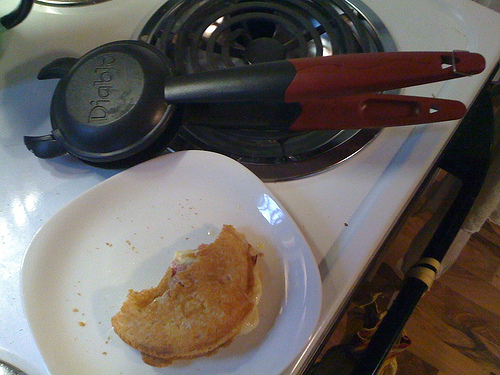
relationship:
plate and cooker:
[21, 148, 326, 373] [23, 0, 485, 183]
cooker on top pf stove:
[23, 0, 485, 183] [3, 0, 498, 373]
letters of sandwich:
[81, 46, 128, 128] [91, 222, 275, 373]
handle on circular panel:
[174, 46, 486, 132] [23, 39, 167, 168]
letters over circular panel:
[81, 46, 128, 128] [20, 36, 160, 168]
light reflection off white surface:
[1, 171, 41, 282] [0, 4, 498, 352]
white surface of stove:
[0, 4, 498, 352] [3, 0, 498, 373]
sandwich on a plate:
[109, 220, 264, 370] [21, 148, 326, 373]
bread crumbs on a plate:
[100, 237, 145, 261] [21, 148, 326, 373]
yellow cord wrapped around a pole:
[405, 254, 443, 294] [330, 82, 495, 373]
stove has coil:
[3, 0, 498, 373] [139, 0, 386, 167]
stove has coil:
[3, 0, 498, 373] [139, 0, 381, 181]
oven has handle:
[266, 92, 485, 373] [398, 146, 456, 368]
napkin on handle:
[338, 251, 444, 373] [357, 146, 486, 374]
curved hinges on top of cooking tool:
[21, 55, 78, 159] [18, 35, 484, 160]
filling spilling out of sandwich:
[233, 255, 272, 359] [237, 272, 257, 322]